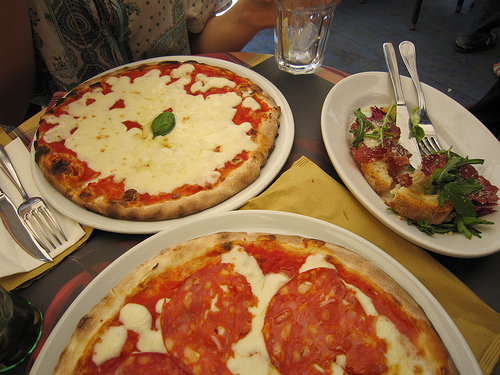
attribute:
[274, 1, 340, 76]
glass — clear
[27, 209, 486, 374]
plate — white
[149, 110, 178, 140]
leaf — basil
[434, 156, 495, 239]
leaves — arugula, green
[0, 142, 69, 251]
fork — silver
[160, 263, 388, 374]
pepperoni — large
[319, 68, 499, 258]
plate — white, oval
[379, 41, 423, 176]
knife — silver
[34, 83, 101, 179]
edge — burned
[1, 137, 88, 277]
napkin — white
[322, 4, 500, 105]
floor — wooden